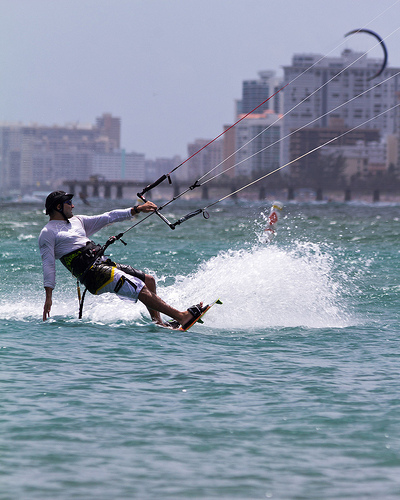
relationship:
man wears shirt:
[32, 185, 224, 332] [33, 208, 134, 292]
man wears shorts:
[32, 185, 224, 332] [76, 263, 153, 307]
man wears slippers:
[32, 185, 224, 332] [159, 294, 212, 335]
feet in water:
[154, 303, 216, 338] [0, 203, 398, 499]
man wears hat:
[32, 185, 224, 332] [40, 190, 78, 219]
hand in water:
[41, 299, 55, 326] [0, 203, 398, 499]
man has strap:
[32, 185, 224, 332] [70, 283, 90, 323]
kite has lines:
[99, 0, 399, 261] [180, 0, 393, 204]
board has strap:
[149, 300, 234, 335] [192, 303, 204, 324]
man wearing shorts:
[32, 185, 224, 332] [76, 263, 153, 307]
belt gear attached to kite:
[61, 232, 139, 279] [99, 0, 399, 261]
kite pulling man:
[99, 0, 399, 261] [32, 185, 224, 332]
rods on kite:
[131, 175, 209, 235] [99, 0, 399, 261]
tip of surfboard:
[198, 304, 217, 321] [149, 300, 234, 335]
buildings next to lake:
[1, 45, 399, 203] [0, 203, 398, 499]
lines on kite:
[180, 0, 393, 204] [99, 0, 399, 261]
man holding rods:
[32, 185, 224, 332] [131, 175, 209, 235]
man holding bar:
[32, 185, 224, 332] [129, 191, 187, 240]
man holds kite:
[32, 185, 224, 332] [99, 0, 399, 261]